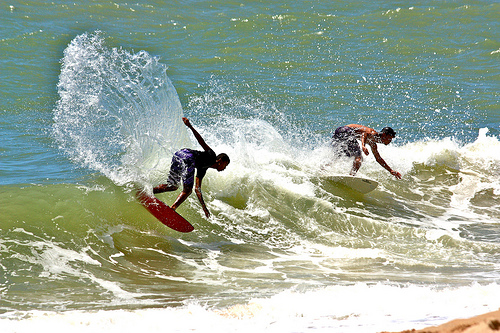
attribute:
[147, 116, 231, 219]
surfer — trying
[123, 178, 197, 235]
surfboard — red, white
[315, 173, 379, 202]
surfboard — white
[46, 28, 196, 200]
splash — water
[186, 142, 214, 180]
shirt — black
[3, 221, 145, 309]
foam — white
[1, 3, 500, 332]
water — calm, foamy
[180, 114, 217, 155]
arm — way out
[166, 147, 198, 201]
pants — blue, dark